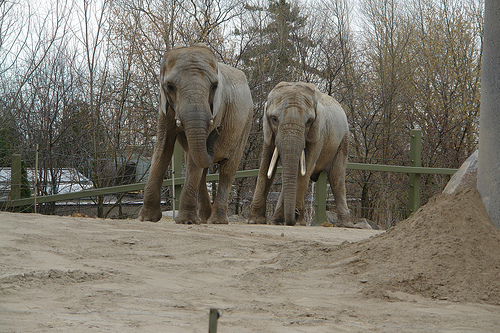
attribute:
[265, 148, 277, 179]
elephant tusk — white, ivory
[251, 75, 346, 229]
elephant — grey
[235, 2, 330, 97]
pine tree — green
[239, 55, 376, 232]
elephant — large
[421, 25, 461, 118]
tree — tall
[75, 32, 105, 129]
tree — tall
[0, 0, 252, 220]
branches — bare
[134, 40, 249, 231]
elephant — large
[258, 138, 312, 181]
tusks — short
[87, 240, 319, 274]
sandy area — brown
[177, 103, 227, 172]
elephant trunk — curled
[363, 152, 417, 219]
fence — green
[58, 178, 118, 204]
exhibit fencing — green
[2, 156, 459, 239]
fence — green, wood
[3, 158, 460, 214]
fence — green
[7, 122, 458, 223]
fence — green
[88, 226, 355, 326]
trail — elephant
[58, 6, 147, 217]
tree — dormant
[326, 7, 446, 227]
tree — dormant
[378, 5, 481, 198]
tree — dormant